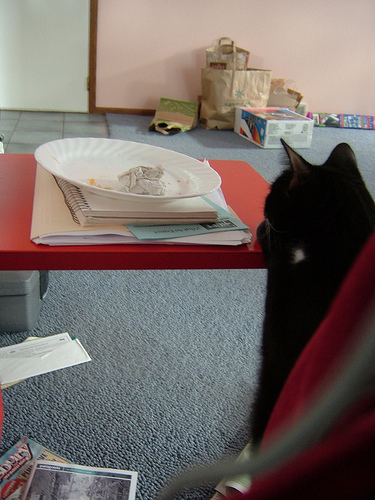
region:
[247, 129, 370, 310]
the cat is black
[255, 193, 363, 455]
the cat is black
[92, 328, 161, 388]
the carpet is gray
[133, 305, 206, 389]
the carpet is gray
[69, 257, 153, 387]
the carpet is gray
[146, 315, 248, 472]
the carpet is gray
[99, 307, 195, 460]
the carpet is gray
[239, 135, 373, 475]
a black cat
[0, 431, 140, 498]
magazines on the floor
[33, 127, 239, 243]
a white plate on a stack of notebooks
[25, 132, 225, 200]
a white plate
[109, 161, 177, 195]
a napkin is crumpled on the plate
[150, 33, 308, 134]
paper bags against the wall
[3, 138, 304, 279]
a red table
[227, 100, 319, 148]
a box is on the floor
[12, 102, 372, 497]
a grey carpet floor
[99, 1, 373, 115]
the wall is pink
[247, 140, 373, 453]
a black and white cat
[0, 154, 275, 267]
an orange table top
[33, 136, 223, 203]
a white plate on the table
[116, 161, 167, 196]
a crumpled up napkin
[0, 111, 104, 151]
a tiled section of floor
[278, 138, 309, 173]
an ear on the cat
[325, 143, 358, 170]
an ear on the cat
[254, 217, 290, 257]
the cat's front paw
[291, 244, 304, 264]
a white spot on the cat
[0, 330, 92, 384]
an envelope on the ground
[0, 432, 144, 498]
MAGAZINES LAYING ON THE FLOOR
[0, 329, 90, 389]
MAIL LAYING ON THE FLOOR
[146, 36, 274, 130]
EMPTY BROWN PAPER SACKS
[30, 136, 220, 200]
WHITE GLASS PLATE ON BOOKS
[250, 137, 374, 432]
BLACK CAT WITH PAWS ON TABLE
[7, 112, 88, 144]
DIRTY GREY FLOOR TILE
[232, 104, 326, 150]
CARDBOARD BOX WITH PICTURE ON IT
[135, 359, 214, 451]
BLUE GREY LOOP CARPET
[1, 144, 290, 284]
RED COFFEE TABLE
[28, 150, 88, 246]
MANILIA FILE FOLDER, SPIRAL NOTEBOOK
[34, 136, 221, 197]
white plate with crumpled paper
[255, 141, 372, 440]
back of black cat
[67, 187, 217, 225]
pad of white paper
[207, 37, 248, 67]
brown bag with handle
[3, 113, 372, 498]
blue carpet on floor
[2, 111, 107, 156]
square tiles on floor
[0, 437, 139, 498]
two booklets on floor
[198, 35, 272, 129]
bag inside another bag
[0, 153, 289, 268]
top of red table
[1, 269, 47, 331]
gray safe on floor